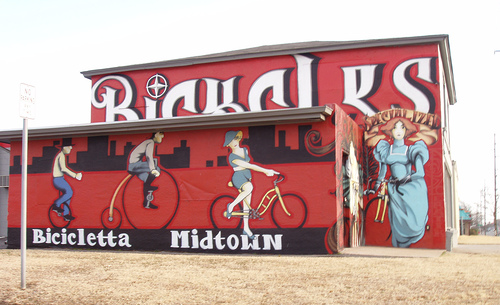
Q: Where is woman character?
A: On wall.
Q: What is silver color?
A: Pole.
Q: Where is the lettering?
A: On building.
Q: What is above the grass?
A: Drawings on wall.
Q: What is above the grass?
A: Drawings on wall.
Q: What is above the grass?
A: Drawings on wall.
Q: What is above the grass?
A: Drawings on wall.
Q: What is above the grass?
A: Art on building.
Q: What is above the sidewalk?
A: Art on building.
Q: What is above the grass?
A: Art on building.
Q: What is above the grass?
A: Art on building.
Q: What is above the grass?
A: Art on building.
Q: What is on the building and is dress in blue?
A: A woman.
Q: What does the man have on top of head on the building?
A: Hat.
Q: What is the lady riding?
A: Bike.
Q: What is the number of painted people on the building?
A: Four.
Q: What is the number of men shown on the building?
A: Two.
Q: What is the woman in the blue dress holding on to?
A: Bicycle.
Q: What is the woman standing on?
A: Bicycle.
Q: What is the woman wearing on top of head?
A: Hat.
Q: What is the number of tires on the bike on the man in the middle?
A: Two.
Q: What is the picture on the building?
A: Bicycles.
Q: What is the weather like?
A: Cloudy.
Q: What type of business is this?
A: Bicycle business.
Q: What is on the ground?
A: Dirt.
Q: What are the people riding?
A: Bikes.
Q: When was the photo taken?
A: Daytime.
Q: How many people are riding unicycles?
A: One.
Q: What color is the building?
A: Red.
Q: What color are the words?
A: White.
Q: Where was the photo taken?
A: In front of a closed business.